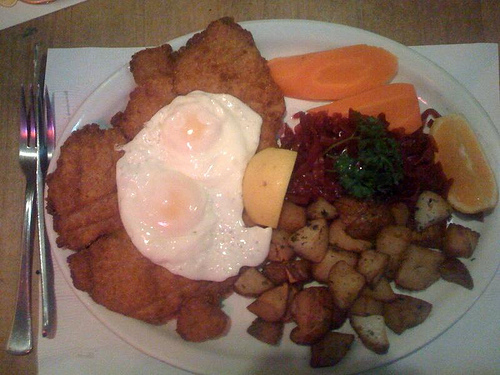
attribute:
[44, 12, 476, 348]
plate — white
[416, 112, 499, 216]
orange slice — sliced, tasty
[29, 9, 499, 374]
plate — white, brown, Red , poured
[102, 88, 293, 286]
eggs — cooked, white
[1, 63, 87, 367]
fork — silver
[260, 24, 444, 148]
carrots — sliced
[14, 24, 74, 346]
knife — silver, shiny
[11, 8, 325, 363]
veges — few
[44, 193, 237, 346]
beef — sliced